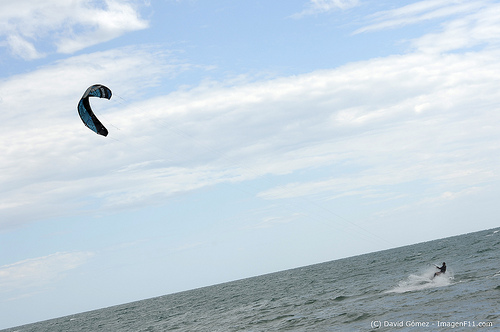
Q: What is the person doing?
A: Parasailing.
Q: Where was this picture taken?
A: Ocean.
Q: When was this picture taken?
A: Daytime.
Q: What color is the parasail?
A: Blue and black.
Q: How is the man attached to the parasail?
A: By string.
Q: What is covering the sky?
A: Clouds.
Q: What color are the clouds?
A: White.